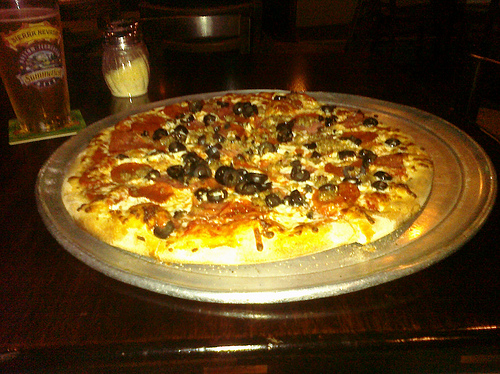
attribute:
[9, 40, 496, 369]
table — brown, long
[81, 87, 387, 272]
pizza — cooked, round, yellow, gold, red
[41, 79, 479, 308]
tray — silver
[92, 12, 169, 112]
jar — clear, white, short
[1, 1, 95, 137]
beer — brown, tall